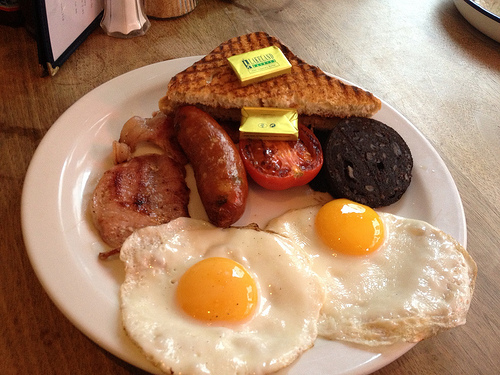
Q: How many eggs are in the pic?
A: 2.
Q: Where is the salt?
A: Above the dish.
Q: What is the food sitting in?
A: A dish.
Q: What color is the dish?
A: White.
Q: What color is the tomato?
A: Red.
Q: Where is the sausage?
A: Between the potato and the tomato.